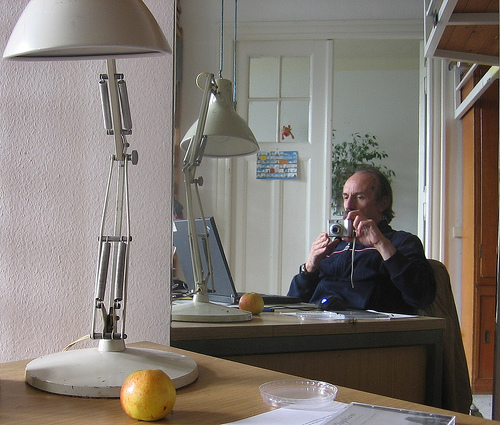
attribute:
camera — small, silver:
[327, 220, 351, 239]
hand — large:
[307, 233, 338, 268]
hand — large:
[344, 212, 383, 251]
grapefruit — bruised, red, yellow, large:
[120, 368, 179, 422]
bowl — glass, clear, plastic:
[259, 380, 338, 406]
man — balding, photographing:
[290, 169, 440, 308]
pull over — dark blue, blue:
[288, 222, 432, 312]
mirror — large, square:
[169, 0, 498, 418]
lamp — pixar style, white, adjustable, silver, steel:
[3, 0, 199, 398]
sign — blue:
[256, 153, 299, 182]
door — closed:
[233, 41, 326, 297]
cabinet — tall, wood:
[462, 71, 499, 394]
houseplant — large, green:
[330, 132, 392, 239]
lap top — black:
[172, 218, 299, 306]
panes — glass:
[247, 57, 310, 141]